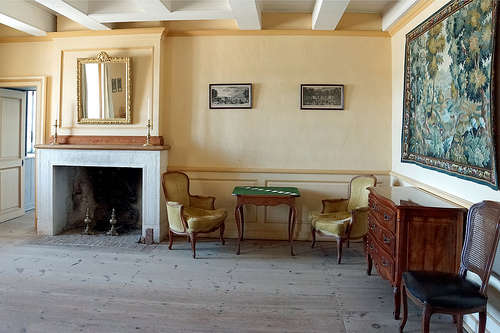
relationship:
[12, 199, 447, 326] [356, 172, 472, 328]
rug beneath dresser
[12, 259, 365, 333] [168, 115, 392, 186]
rug on wall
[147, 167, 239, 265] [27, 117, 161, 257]
chair next to fireplace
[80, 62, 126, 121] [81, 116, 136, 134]
mirror in frame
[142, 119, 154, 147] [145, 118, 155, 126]
candelabrum with candle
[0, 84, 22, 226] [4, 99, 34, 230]
door into hallway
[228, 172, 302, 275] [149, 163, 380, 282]
table between chairs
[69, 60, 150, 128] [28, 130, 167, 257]
mirror above fireplace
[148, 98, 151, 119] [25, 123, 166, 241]
candle on fireplace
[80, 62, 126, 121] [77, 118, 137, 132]
mirror with frame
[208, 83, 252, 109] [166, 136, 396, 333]
frame on wall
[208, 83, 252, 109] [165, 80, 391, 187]
frame covering wall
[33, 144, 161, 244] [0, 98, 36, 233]
fireplace next to door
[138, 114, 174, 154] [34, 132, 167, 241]
candle next to fireplace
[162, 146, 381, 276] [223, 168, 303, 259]
chairs on table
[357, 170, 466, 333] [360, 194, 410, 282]
chest with drawers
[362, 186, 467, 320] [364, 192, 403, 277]
chest with drawers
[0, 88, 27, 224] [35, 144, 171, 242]
door open next to fireplace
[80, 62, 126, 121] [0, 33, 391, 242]
mirror hanging on wall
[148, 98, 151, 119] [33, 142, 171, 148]
candle sitting on top of mantle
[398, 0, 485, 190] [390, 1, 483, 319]
rug hanging on wall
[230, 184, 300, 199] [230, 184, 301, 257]
top belonging to table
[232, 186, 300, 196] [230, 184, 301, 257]
top belonging to table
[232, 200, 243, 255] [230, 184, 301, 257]
leg holding up table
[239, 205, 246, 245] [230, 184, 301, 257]
leg holding up table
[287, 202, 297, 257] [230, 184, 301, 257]
leg holding up table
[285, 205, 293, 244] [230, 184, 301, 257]
leg holding up table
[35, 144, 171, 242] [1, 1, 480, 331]
fireplace sitting inside room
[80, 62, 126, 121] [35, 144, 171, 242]
mirror hanging above fireplace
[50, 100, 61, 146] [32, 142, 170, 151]
candelabrum sitting on top of mantle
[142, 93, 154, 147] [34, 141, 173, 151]
candelabrum sitting on top of mantle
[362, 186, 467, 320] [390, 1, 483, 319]
chest standing against wall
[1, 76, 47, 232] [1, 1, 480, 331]
doorway leading to room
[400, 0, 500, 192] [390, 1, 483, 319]
rug hanging on wall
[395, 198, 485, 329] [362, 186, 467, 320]
chair standing next to chest